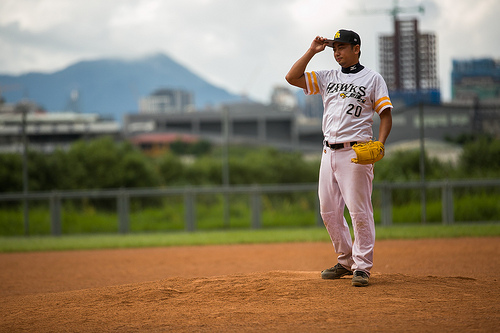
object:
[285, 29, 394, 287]
player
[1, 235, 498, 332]
court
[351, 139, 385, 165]
mitt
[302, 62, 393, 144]
shirt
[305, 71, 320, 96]
stripes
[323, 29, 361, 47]
cap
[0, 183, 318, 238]
fence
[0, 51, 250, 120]
hill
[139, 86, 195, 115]
building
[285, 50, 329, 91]
arm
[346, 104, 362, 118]
number 20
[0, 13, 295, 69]
background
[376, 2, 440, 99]
building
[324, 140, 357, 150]
belt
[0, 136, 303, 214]
trees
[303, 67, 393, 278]
uniform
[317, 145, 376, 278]
pants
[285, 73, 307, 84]
elbow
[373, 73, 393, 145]
left arm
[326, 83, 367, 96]
name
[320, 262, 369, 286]
shoes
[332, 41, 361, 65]
head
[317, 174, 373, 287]
legs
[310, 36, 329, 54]
hand